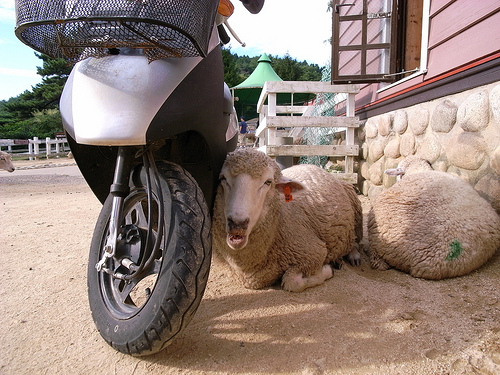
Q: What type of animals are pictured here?
A: Sheep.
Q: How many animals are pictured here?
A: Two.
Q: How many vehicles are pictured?
A: One.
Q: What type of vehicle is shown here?
A: Motorcycle.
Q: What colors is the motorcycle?
A: Black and grey.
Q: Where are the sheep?
A: On the ground.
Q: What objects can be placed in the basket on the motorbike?
A: Small items.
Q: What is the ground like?
A: Sand.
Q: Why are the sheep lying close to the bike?
A: There is shade.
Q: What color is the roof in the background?
A: Green.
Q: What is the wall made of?
A: Stones.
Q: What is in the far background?
A: Trees.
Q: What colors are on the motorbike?
A: Silver and black.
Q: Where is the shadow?
A: On the ground.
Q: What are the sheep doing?
A: Sitting.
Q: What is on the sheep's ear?
A: Tag.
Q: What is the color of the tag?
A: Green.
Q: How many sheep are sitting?
A: 2.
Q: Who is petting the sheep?
A: No one.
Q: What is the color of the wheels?
A: Black.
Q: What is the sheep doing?
A: Laying down.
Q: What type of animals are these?
A: Sheep.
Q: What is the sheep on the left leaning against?
A: Bike.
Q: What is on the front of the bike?
A: Basket.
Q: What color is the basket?
A: Black.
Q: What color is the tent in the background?
A: Green.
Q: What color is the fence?
A: White.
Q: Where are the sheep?
A: To the right of the motorcycle.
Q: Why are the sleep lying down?
A: They are resting.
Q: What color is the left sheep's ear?
A: Red.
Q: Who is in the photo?
A: Nobody.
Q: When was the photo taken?
A: Daytime.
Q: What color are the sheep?
A: White.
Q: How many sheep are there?
A: Two.